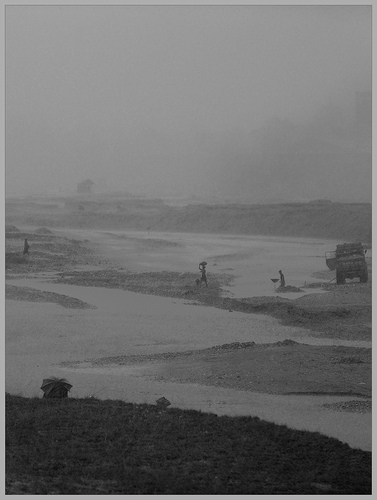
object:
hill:
[6, 389, 374, 492]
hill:
[135, 197, 373, 239]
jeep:
[325, 243, 369, 285]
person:
[199, 261, 208, 288]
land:
[62, 339, 371, 398]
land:
[2, 228, 377, 339]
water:
[1, 311, 101, 344]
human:
[278, 270, 285, 288]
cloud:
[1, 2, 373, 180]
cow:
[156, 396, 171, 413]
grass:
[36, 434, 324, 485]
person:
[22, 238, 29, 256]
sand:
[12, 261, 50, 276]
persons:
[40, 375, 72, 397]